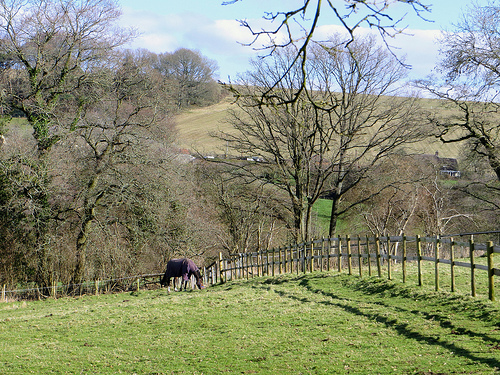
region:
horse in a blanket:
[148, 252, 212, 299]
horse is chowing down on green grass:
[153, 254, 207, 299]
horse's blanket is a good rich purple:
[156, 254, 197, 281]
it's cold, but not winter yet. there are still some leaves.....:
[0, 1, 197, 317]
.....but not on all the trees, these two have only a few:
[192, 0, 447, 298]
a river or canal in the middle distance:
[194, 226, 498, 283]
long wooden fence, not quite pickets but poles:
[201, 226, 498, 305]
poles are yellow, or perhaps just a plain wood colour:
[201, 223, 498, 305]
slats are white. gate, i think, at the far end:
[197, 229, 497, 305]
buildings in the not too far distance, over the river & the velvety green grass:
[130, 142, 465, 175]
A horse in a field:
[166, 258, 206, 293]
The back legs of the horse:
[160, 277, 179, 292]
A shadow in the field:
[271, 273, 493, 373]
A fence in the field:
[213, 237, 498, 294]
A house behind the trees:
[436, 155, 459, 175]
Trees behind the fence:
[246, 10, 448, 252]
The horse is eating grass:
[163, 258, 208, 290]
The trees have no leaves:
[356, 175, 462, 249]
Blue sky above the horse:
[3, 0, 498, 101]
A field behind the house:
[177, 79, 498, 153]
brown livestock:
[157, 255, 207, 295]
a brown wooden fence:
[202, 230, 497, 301]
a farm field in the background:
[145, 79, 497, 172]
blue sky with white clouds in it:
[6, 0, 498, 107]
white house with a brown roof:
[412, 151, 463, 176]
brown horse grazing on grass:
[160, 255, 209, 296]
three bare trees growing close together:
[196, 26, 440, 285]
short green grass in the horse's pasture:
[0, 270, 498, 373]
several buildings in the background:
[162, 141, 302, 171]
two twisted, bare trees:
[1, 3, 179, 302]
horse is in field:
[150, 260, 212, 287]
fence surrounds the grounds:
[222, 244, 499, 298]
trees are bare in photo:
[250, 43, 354, 252]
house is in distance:
[227, 147, 269, 164]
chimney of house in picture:
[429, 146, 439, 162]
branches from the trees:
[133, 191, 183, 250]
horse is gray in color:
[141, 250, 220, 297]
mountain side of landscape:
[198, 98, 476, 149]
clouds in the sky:
[195, 35, 247, 84]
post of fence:
[130, 267, 145, 309]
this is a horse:
[163, 255, 206, 297]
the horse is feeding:
[166, 252, 206, 292]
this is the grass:
[213, 285, 329, 365]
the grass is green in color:
[222, 287, 302, 373]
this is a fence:
[353, 231, 417, 273]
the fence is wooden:
[351, 225, 450, 282]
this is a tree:
[260, 63, 384, 218]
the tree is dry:
[267, 85, 367, 217]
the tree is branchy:
[55, 115, 136, 254]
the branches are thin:
[291, 5, 362, 52]